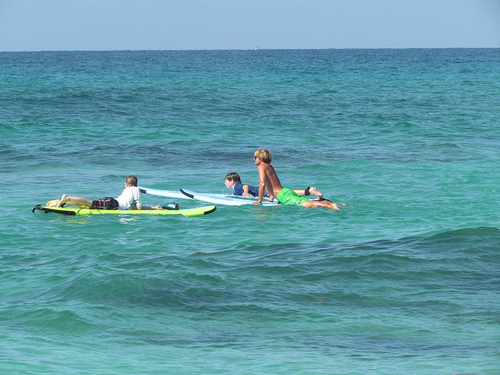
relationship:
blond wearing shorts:
[250, 144, 342, 211] [276, 188, 313, 208]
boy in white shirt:
[56, 171, 168, 213] [117, 182, 147, 212]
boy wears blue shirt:
[221, 171, 325, 197] [232, 180, 269, 199]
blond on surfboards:
[250, 144, 342, 211] [53, 191, 305, 216]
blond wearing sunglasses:
[250, 144, 342, 211] [249, 154, 262, 161]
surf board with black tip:
[179, 185, 280, 208] [179, 188, 192, 203]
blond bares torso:
[250, 144, 342, 211] [252, 167, 280, 192]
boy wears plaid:
[56, 171, 168, 213] [90, 195, 117, 209]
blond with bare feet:
[250, 144, 342, 211] [304, 182, 345, 212]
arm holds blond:
[259, 167, 267, 205] [250, 144, 342, 211]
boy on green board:
[56, 171, 168, 213] [28, 201, 217, 219]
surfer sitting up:
[250, 144, 342, 211] [252, 144, 277, 208]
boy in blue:
[221, 171, 325, 197] [236, 180, 248, 194]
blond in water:
[250, 144, 342, 211] [6, 63, 500, 359]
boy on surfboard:
[56, 171, 168, 213] [179, 185, 280, 208]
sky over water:
[2, 2, 500, 50] [6, 63, 500, 359]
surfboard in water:
[179, 185, 280, 208] [6, 63, 500, 359]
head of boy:
[224, 167, 241, 194] [221, 171, 325, 197]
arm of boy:
[259, 167, 267, 205] [250, 144, 342, 211]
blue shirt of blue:
[234, 182, 260, 196] [236, 180, 248, 194]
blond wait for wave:
[250, 144, 342, 211] [16, 218, 500, 337]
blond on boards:
[250, 144, 342, 211] [53, 191, 305, 216]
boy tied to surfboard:
[221, 171, 325, 197] [179, 185, 280, 208]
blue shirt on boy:
[232, 180, 269, 199] [221, 171, 325, 197]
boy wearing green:
[250, 144, 342, 211] [277, 184, 325, 204]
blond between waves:
[250, 144, 342, 211] [6, 129, 500, 272]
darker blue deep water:
[1, 49, 499, 72] [6, 63, 500, 359]